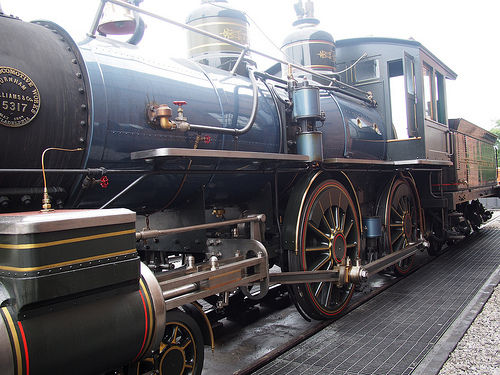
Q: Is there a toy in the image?
A: No, there are no toys.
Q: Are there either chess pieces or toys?
A: No, there are no toys or chess pieces.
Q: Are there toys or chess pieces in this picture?
A: No, there are no toys or chess pieces.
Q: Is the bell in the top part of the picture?
A: Yes, the bell is in the top of the image.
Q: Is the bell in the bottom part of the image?
A: No, the bell is in the top of the image.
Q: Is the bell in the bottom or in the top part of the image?
A: The bell is in the top of the image.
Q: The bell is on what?
A: The bell is on the train.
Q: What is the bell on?
A: The bell is on the train.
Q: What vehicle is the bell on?
A: The bell is on the train.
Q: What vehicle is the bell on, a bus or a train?
A: The bell is on a train.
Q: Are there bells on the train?
A: Yes, there is a bell on the train.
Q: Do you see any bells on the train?
A: Yes, there is a bell on the train.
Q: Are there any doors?
A: Yes, there is a door.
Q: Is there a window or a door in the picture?
A: Yes, there is a door.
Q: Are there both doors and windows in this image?
A: Yes, there are both a door and a window.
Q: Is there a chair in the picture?
A: No, there are no chairs.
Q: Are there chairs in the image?
A: No, there are no chairs.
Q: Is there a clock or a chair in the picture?
A: No, there are no chairs or clocks.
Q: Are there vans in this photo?
A: No, there are no vans.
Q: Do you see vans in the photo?
A: No, there are no vans.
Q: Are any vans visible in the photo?
A: No, there are no vans.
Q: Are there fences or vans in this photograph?
A: No, there are no vans or fences.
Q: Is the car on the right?
A: Yes, the car is on the right of the image.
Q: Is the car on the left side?
A: No, the car is on the right of the image.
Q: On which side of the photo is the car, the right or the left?
A: The car is on the right of the image.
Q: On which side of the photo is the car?
A: The car is on the right of the image.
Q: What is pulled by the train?
A: The car is pulled by the train.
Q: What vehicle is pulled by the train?
A: The vehicle is a car.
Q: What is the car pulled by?
A: The car is pulled by the train.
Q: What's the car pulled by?
A: The car is pulled by the train.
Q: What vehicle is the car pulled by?
A: The car is pulled by the train.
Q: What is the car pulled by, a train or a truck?
A: The car is pulled by a train.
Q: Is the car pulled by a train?
A: Yes, the car is pulled by a train.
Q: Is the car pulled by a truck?
A: No, the car is pulled by a train.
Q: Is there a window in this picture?
A: Yes, there is a window.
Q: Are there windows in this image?
A: Yes, there is a window.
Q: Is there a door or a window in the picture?
A: Yes, there is a window.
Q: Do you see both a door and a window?
A: Yes, there are both a window and a door.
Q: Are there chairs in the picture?
A: No, there are no chairs.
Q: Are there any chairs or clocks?
A: No, there are no chairs or clocks.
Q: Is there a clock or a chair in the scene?
A: No, there are no chairs or clocks.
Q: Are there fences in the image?
A: No, there are no fences.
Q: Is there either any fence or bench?
A: No, there are no fences or benches.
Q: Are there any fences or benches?
A: No, there are no fences or benches.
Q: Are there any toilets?
A: No, there are no toilets.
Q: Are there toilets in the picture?
A: No, there are no toilets.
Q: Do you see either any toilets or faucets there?
A: No, there are no toilets or faucets.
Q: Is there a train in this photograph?
A: Yes, there is a train.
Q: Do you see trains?
A: Yes, there is a train.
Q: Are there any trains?
A: Yes, there is a train.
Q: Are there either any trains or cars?
A: Yes, there is a train.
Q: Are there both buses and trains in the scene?
A: No, there is a train but no buses.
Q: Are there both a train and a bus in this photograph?
A: No, there is a train but no buses.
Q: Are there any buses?
A: No, there are no buses.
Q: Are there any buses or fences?
A: No, there are no buses or fences.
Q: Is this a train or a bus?
A: This is a train.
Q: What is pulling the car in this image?
A: The train is pulling the car.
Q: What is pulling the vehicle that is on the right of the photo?
A: The train is pulling the car.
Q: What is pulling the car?
A: The train is pulling the car.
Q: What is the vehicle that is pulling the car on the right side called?
A: The vehicle is a train.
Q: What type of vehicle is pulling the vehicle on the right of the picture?
A: The vehicle is a train.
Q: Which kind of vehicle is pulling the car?
A: The vehicle is a train.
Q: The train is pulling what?
A: The train is pulling the car.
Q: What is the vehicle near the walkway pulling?
A: The train is pulling the car.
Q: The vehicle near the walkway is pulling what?
A: The train is pulling the car.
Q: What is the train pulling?
A: The train is pulling the car.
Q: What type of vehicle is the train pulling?
A: The train is pulling the car.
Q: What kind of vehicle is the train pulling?
A: The train is pulling the car.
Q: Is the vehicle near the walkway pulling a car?
A: Yes, the train is pulling a car.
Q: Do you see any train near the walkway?
A: Yes, there is a train near the walkway.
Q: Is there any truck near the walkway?
A: No, there is a train near the walkway.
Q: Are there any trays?
A: No, there are no trays.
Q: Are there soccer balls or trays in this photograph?
A: No, there are no trays or soccer balls.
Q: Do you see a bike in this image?
A: No, there are no bikes.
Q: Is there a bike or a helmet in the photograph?
A: No, there are no bikes or helmets.